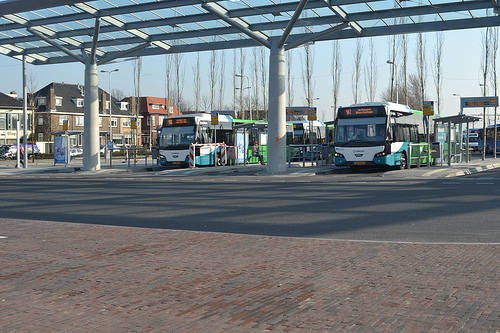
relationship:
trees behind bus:
[154, 5, 494, 137] [334, 101, 452, 170]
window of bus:
[333, 115, 386, 142] [334, 101, 452, 170]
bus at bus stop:
[334, 101, 452, 170] [4, 5, 497, 215]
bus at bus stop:
[151, 112, 294, 167] [4, 5, 497, 215]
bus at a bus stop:
[334, 101, 452, 170] [0, 5, 496, 241]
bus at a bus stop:
[163, 110, 254, 172] [0, 5, 496, 241]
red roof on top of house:
[135, 93, 185, 115] [1, 90, 39, 154]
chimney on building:
[49, 89, 59, 111] [27, 80, 142, 156]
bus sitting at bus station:
[319, 89, 423, 178] [254, 24, 476, 194]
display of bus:
[335, 107, 387, 118] [332, 97, 437, 174]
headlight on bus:
[157, 152, 165, 159] [154, 109, 266, 162]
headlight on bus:
[374, 150, 387, 157] [332, 97, 437, 174]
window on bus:
[333, 115, 386, 142] [324, 96, 430, 176]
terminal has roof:
[0, 1, 497, 174] [1, 0, 498, 63]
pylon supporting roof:
[265, 41, 287, 176] [1, 0, 498, 63]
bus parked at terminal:
[334, 101, 452, 170] [0, 1, 497, 174]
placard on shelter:
[46, 129, 76, 172] [43, 117, 81, 168]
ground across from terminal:
[8, 163, 498, 243] [0, 1, 497, 174]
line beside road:
[1, 204, 495, 251] [3, 216, 498, 332]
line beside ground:
[1, 204, 495, 251] [8, 163, 498, 243]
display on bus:
[164, 111, 193, 125] [152, 112, 269, 169]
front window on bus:
[161, 125, 199, 152] [156, 112, 291, 173]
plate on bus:
[163, 151, 190, 173] [156, 106, 238, 166]